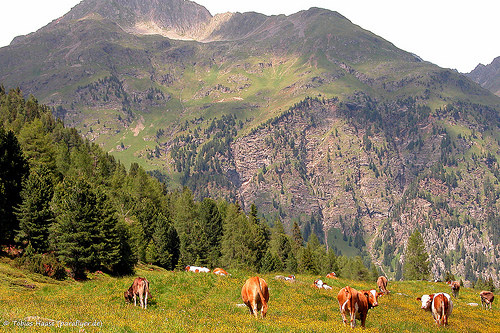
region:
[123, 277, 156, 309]
brown cow eating grass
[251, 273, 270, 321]
brown tail of a cow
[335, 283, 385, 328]
brown and white cow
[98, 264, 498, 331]
cows on a grassy field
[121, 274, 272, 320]
two cows standing on a field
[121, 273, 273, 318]
two brown cows on a grassy field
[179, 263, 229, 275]
two cows laying down on grass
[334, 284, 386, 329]
cow with a white spot on its head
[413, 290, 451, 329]
brown cow with a white face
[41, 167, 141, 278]
thick green pine tree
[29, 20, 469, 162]
green grass on the hillside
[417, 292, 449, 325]
brown and white cow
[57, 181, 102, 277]
a tall evergreen tree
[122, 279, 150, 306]
the cow is grazing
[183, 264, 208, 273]
white cow with brown spots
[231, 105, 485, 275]
rocky side of the mountain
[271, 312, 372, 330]
yellow wildflowers in the field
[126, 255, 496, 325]
a herd of cows grazing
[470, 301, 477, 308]
a large white rock in the field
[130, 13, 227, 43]
sun shining on the mountain side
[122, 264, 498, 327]
cows on a green grass field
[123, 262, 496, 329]
cows grazing in a field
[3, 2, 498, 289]
rocky mountains with grass on them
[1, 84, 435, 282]
trees on the side of a mountain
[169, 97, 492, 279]
cliff on the side of a mountain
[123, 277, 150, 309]
cow grazing on some green grass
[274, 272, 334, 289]
two cows laying down in grass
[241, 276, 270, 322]
rear view of a cow eating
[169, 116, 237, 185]
trees on the side of a mountain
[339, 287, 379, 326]
side view of a cow on a mountain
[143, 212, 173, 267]
a tree on the side of a mountain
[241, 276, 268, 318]
the back side of a brown cow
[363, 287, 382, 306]
the face of a brown cow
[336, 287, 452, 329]
two brown cows in the field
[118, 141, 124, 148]
tree in the moutain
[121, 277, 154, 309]
cow eating grass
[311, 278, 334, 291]
a cow laying in the grass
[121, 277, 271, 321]
two cows in the grass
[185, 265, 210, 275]
a mostly white but a little brown cow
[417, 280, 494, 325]
three cows in the field